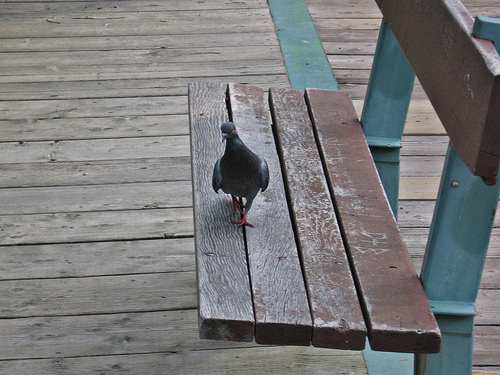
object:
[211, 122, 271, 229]
bird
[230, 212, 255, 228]
feet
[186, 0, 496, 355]
bench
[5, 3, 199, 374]
floor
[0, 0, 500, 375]
photo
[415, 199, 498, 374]
metal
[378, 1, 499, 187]
back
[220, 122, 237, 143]
head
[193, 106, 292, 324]
forward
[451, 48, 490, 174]
boards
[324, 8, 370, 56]
part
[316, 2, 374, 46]
ground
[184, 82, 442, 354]
wood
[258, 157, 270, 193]
right wing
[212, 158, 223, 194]
left wing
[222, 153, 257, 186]
chest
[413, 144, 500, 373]
pole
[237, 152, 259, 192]
feathers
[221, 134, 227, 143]
grey beak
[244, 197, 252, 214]
leg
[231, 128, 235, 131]
eye